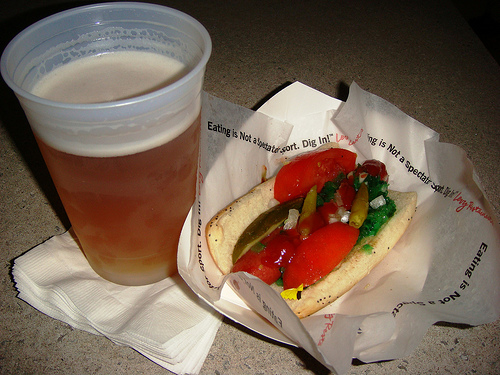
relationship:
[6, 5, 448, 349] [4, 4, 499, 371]
things in floor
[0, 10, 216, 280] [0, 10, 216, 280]
cup has drink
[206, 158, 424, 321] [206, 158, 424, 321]
bun in bun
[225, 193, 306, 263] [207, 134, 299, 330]
pickle on side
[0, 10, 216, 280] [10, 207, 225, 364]
cup on napkins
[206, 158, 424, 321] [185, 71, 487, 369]
bun on paper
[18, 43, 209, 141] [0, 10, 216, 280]
foam tops drink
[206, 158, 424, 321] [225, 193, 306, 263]
bun has pickle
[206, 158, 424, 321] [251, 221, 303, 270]
bun has ketchup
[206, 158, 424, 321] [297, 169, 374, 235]
bun has peppers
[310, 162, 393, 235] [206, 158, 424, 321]
relish on bun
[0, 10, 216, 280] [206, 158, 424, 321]
drink with bun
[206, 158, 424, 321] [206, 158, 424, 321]
bun has bun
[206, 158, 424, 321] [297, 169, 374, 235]
bun has pepper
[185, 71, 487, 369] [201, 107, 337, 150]
paper has wording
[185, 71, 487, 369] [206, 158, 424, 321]
paper beneath bun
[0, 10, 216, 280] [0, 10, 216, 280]
drink in cup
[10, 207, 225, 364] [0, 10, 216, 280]
napkins beneath cup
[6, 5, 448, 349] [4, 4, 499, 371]
lunch on counter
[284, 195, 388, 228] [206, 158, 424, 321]
onion on bun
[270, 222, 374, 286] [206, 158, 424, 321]
pepper in bun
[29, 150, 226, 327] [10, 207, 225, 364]
napkins in napkins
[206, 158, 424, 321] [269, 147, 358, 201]
bun has tomatoes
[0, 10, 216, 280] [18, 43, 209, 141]
drink has foam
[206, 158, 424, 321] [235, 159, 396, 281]
bun has toppings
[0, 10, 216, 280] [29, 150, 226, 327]
cup on napkins